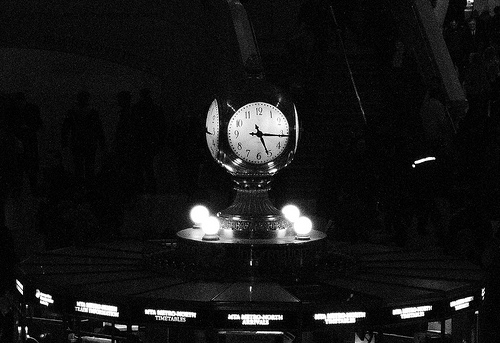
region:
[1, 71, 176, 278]
a group of people in the shadows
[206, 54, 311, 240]
a clock on a pedestal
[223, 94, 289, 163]
the face of a clock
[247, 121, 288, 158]
the hands of a clock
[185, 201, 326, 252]
four lights on a pedestal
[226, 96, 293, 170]
a lit clock face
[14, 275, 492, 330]
several lit signs with words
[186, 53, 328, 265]
this is a clock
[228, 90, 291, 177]
white face on clock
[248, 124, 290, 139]
hour hand on clock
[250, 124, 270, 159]
minute hand on clock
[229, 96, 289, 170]
black numbers on clock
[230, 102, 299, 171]
standard numbers on clock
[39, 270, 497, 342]
set of lit up lights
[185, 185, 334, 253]
lights around the clock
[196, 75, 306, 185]
globe with clocks on several sides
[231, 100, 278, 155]
clock on one side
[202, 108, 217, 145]
clock on one side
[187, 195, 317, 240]
lit lights beneath globe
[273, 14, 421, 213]
stairs leading to upper area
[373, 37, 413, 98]
people on the stairs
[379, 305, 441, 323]
lit lettering on architecture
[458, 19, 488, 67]
people next to stairs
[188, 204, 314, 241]
four light bulbs on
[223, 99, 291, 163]
clock showing that it is 5:16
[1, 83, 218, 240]
people standing around waiting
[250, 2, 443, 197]
people walking up and down stairs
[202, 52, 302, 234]
clock with four sides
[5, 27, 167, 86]
brick arch on wall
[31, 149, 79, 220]
man sitting down on bench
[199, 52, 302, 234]
clock with four round clock faces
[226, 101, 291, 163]
round white clock face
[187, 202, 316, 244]
light bulbs that are turned on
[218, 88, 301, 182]
a black and white clock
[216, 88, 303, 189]
clock reads 5 15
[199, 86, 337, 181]
clock has 4 sides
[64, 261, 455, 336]
words can be read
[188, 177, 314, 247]
4 lights under clock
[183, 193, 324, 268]
4 lights are bright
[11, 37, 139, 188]
all is dark black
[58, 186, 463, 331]
a large black table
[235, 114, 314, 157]
long hands on clock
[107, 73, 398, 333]
this is a large clock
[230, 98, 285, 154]
clock on the ball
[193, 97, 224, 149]
clock on the ball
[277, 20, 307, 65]
person riding the escalator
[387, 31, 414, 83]
person riding the escalator